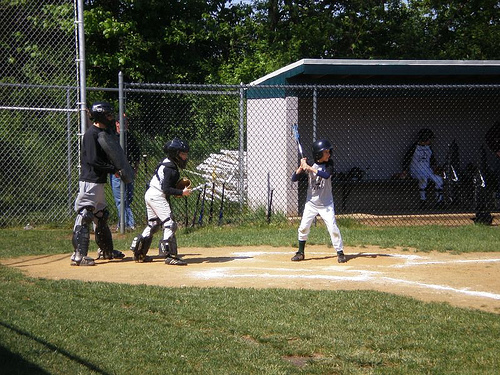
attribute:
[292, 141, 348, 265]
boy — young, batting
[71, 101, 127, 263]
umpire — in black, in grey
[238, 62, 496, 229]
dugout — gray, green, dark green, white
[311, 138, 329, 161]
helmet — navy blue, black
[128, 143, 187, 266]
boy — catcher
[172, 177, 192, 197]
mitt — brown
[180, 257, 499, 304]
lines — white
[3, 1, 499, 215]
fence — silver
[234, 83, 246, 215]
posts — grey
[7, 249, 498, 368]
field — dry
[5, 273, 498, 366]
grass — green, cut, mowed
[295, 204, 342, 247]
pants — white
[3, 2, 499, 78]
trees — green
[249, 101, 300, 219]
wall — light gray, stone